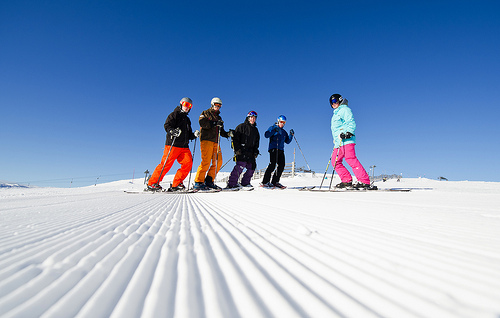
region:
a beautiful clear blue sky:
[1, 0, 498, 185]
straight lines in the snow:
[2, 193, 439, 315]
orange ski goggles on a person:
[180, 98, 194, 108]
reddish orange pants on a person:
[148, 144, 194, 182]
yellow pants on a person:
[194, 140, 224, 183]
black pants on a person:
[262, 148, 290, 179]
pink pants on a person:
[330, 144, 371, 181]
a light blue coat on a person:
[329, 105, 355, 146]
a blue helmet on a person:
[277, 112, 289, 123]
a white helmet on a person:
[209, 95, 224, 107]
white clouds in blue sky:
[31, 15, 66, 35]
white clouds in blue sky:
[386, 75, 436, 122]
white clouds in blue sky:
[285, 28, 340, 79]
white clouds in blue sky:
[218, 31, 248, 49]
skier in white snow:
[153, 87, 193, 182]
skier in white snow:
[192, 95, 227, 181]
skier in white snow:
[227, 105, 268, 196]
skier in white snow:
[263, 105, 293, 200]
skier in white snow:
[314, 79, 382, 220]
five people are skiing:
[138, 55, 393, 218]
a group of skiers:
[108, 69, 418, 227]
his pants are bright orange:
[131, 135, 202, 188]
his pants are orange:
[197, 140, 233, 189]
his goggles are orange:
[173, 95, 202, 107]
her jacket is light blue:
[320, 100, 382, 150]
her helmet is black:
[323, 85, 349, 112]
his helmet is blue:
[272, 100, 291, 132]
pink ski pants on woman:
[326, 138, 388, 191]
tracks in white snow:
[213, 211, 251, 314]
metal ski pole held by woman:
[318, 140, 331, 191]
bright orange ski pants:
[126, 122, 185, 193]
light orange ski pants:
[196, 132, 226, 194]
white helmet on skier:
[210, 95, 227, 110]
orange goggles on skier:
[164, 91, 212, 121]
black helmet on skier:
[319, 87, 370, 126]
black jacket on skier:
[160, 112, 210, 144]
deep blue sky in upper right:
[344, 22, 412, 83]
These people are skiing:
[154, 76, 390, 213]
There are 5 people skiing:
[152, 70, 384, 201]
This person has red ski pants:
[142, 134, 197, 197]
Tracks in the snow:
[35, 186, 430, 316]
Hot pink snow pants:
[323, 140, 380, 190]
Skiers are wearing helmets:
[176, 85, 359, 131]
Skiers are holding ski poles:
[141, 118, 377, 215]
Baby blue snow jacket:
[320, 107, 367, 151]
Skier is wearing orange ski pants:
[190, 130, 230, 192]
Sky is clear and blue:
[3, 3, 497, 185]